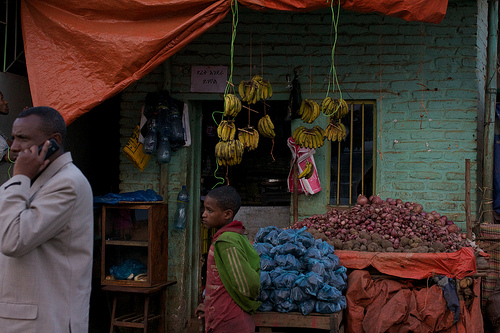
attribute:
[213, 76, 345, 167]
bananas — yellow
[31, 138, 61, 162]
phone — black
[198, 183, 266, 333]
boy — standing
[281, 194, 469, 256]
onions — red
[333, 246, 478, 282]
table — covered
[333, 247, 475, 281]
tablecloth — red, plastic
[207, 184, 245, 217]
hair — black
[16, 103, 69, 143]
hair — black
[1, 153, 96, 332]
jacket — tan, green, beige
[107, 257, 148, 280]
bag — blue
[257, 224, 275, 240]
bag — blue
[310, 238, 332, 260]
bag — blue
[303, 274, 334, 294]
bag — blue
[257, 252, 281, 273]
bag — blue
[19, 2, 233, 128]
tarp — orange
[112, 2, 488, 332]
building — green, brick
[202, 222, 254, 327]
shirt — red, yellow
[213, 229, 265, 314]
jacket — green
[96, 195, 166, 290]
shelves — wood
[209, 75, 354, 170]
bananas — hanging, yellow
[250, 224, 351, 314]
bags — tied, blue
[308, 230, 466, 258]
potatoes — piled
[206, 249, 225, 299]
decal — yellow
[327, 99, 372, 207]
bars — yellow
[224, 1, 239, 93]
ropes — green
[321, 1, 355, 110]
ropes — green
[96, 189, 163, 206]
bag — blue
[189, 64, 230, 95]
sign — white